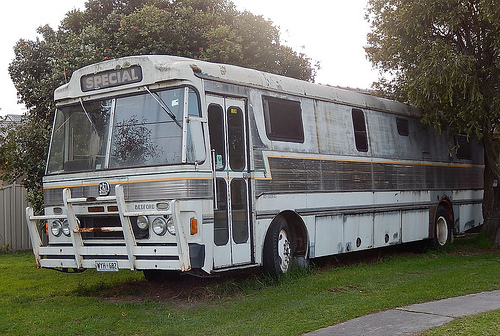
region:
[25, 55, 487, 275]
the old bus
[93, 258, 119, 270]
the white license plate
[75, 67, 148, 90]
the word SPECIAL on the top of the bus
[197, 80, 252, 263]
the door on the side of the bus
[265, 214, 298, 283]
the front wheel near the door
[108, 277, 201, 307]
the dirt under the bus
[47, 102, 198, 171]
the windshield on the bus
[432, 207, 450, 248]
the rear wheel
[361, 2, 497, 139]
the tree touching the bus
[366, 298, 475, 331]
the gray sidewalk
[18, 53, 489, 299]
A bus on the yard.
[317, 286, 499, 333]
A sidewalk on the lawn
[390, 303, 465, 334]
Line with grass in it.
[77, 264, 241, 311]
Dirt patch under the bus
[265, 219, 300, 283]
The wheel on the bus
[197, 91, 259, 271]
The door to the bus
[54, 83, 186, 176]
The windshield of the bus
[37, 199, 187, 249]
The head lights.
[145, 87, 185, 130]
Windshield wipe on the bus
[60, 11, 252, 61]
Fruit in the tree.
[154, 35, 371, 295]
a trailer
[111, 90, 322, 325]
a trailer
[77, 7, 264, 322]
a trailer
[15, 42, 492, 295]
slightly grimy, faded big bus parked on lawn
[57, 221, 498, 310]
grass beneath bus dead &/or departed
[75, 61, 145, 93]
bus is 'special' & will be glad to tell you!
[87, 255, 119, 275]
white license plate w/ dark printing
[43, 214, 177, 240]
four, probably six, clear headlamps w/ a rusted metal bicycle bar between them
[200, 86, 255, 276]
requisite bus accordion bus double door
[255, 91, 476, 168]
uniquely shaped windows @ side of bus: rectangular, ovular, tiny, almost impossible to see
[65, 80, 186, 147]
both windscreen wipers lean from bus' left to right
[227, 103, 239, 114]
yellow tag @ top of right bus door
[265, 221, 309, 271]
@ least one white hubcap w/ convex lugnuts, etc & ect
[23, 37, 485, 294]
white bus parked in the grass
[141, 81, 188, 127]
windshield wiper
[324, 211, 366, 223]
black spots on the side of the bus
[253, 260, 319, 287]
tall grass growing by the wheel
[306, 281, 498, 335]
sidewalk running throught the grass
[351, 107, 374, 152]
small black window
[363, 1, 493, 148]
tree top growing over the bus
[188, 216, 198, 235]
small orange light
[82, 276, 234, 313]
dirt under the bus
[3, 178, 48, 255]
small fence